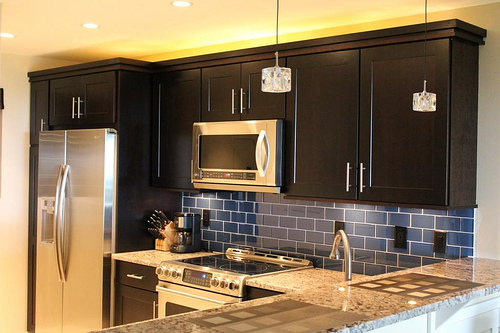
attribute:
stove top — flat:
[173, 250, 304, 275]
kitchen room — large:
[0, 0, 485, 331]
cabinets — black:
[298, 37, 455, 256]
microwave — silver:
[156, 111, 339, 242]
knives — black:
[136, 204, 173, 237]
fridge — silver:
[28, 124, 121, 222]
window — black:
[200, 136, 261, 167]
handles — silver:
[339, 160, 368, 209]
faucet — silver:
[324, 219, 359, 298]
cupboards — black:
[169, 60, 241, 117]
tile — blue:
[215, 208, 238, 239]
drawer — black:
[112, 260, 164, 284]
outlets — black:
[390, 225, 415, 261]